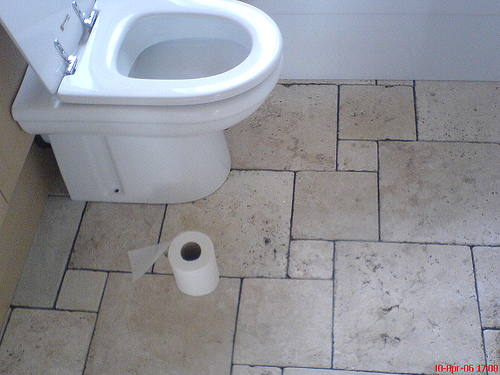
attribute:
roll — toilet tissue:
[116, 224, 264, 332]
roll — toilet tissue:
[127, 230, 219, 295]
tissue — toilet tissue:
[128, 230, 218, 296]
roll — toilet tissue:
[96, 221, 293, 313]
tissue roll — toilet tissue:
[120, 214, 264, 351]